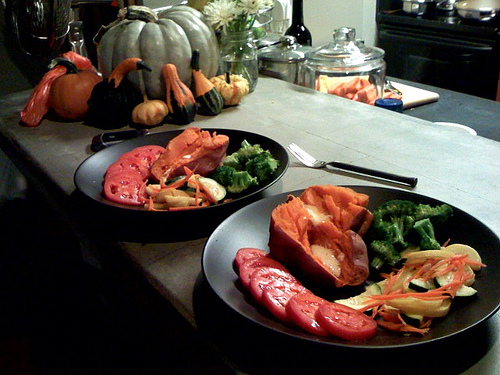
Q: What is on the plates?
A: Food.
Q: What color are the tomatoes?
A: Red.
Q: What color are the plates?
A: Black.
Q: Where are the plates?
A: On counter.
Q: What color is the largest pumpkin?
A: Gray.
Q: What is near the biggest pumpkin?
A: Gourds.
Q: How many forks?
A: One.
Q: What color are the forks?
A: Silver.